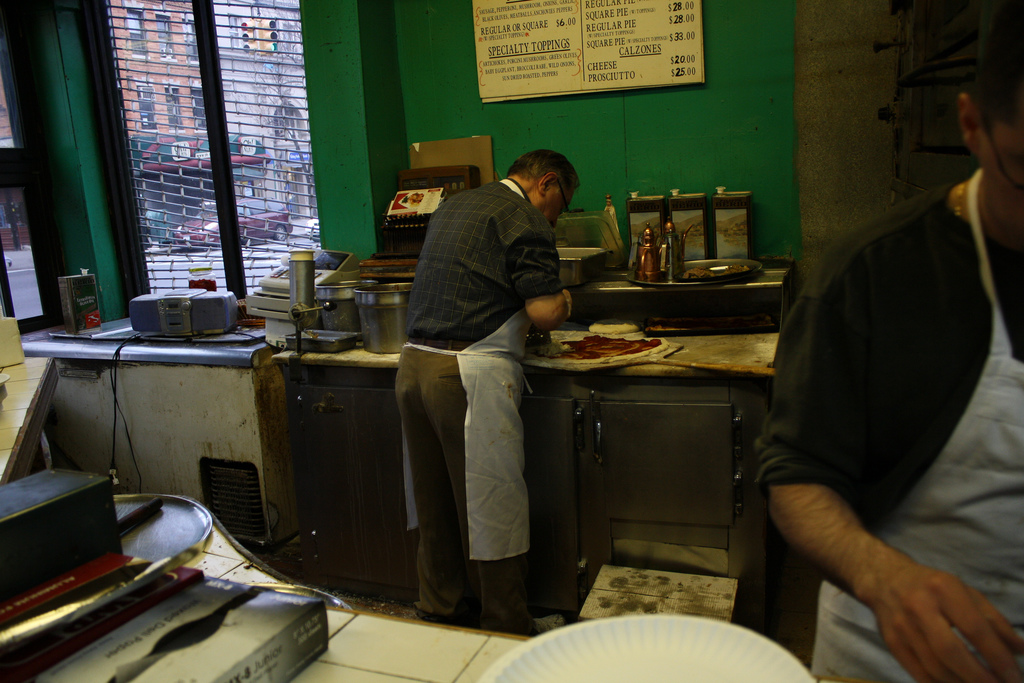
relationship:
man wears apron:
[380, 140, 591, 637] [405, 300, 529, 570]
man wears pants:
[380, 140, 591, 637] [394, 341, 534, 629]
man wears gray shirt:
[380, 140, 591, 637] [402, 172, 564, 343]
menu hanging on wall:
[458, 0, 718, 110] [646, 102, 787, 176]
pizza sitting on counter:
[541, 324, 677, 363] [685, 321, 759, 382]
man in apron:
[729, 17, 1024, 679] [445, 325, 566, 576]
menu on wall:
[416, 0, 794, 125] [648, 116, 748, 162]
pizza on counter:
[540, 324, 675, 363] [669, 329, 750, 394]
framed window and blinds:
[73, 6, 130, 261] [218, 36, 312, 166]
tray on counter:
[620, 231, 761, 286] [669, 336, 758, 376]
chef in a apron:
[398, 144, 582, 635] [449, 325, 525, 567]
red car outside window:
[132, 142, 300, 253] [97, 6, 298, 288]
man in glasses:
[397, 140, 629, 637] [540, 193, 573, 219]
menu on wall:
[458, 0, 718, 110] [577, 111, 690, 179]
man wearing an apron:
[729, 17, 1023, 679] [823, 219, 1022, 678]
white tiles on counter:
[296, 601, 524, 679] [354, 598, 478, 678]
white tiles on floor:
[571, 556, 740, 629] [581, 554, 685, 606]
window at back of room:
[73, 1, 333, 321] [3, 5, 991, 664]